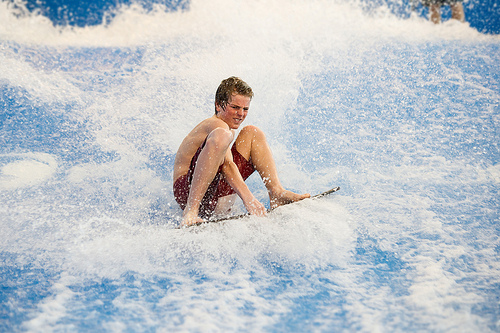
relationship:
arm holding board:
[216, 119, 267, 220] [148, 183, 355, 231]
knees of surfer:
[203, 124, 268, 149] [171, 75, 316, 230]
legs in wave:
[423, 1, 478, 28] [71, 225, 361, 266]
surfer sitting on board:
[171, 75, 316, 230] [151, 181, 341, 234]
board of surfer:
[151, 181, 341, 234] [171, 69, 316, 229]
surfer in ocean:
[171, 69, 316, 229] [10, 5, 485, 325]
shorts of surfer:
[173, 143, 253, 217] [171, 69, 316, 229]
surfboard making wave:
[130, 173, 357, 236] [57, 222, 362, 276]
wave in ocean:
[57, 222, 362, 276] [10, 5, 485, 325]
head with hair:
[215, 77, 252, 128] [213, 75, 253, 114]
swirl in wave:
[2, 117, 87, 219] [0, 7, 175, 274]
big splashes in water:
[325, 33, 374, 102] [1, 5, 488, 327]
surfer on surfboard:
[171, 75, 316, 230] [146, 184, 356, 251]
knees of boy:
[211, 125, 290, 155] [165, 71, 325, 226]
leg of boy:
[182, 123, 234, 224] [166, 72, 316, 213]